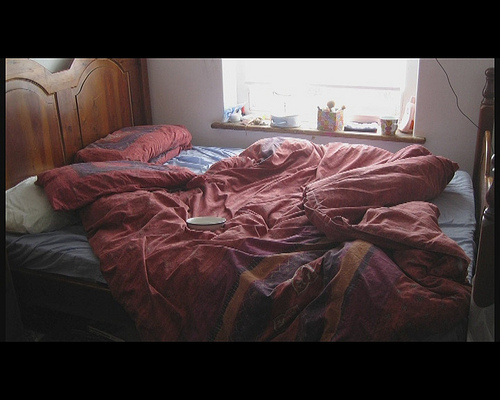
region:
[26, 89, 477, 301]
a messy unmade bed with a white bowl in it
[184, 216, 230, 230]
a white bowl on top of the duvet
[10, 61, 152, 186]
a dark wood headboard on the bed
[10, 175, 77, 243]
a white pillow near the headboard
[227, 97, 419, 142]
a bunch of stuff on the window sill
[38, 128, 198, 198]
two pillows with cases that match the duvet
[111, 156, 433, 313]
a rumpled pink duvet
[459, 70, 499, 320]
a wooden frame at the foot of the bed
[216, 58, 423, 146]
a window next to the bed with no covering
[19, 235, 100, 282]
white sheets on the mattress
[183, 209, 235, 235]
The white bowl on the bed.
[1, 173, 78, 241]
The white pillow on the bed.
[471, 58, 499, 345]
The foot board of the bed.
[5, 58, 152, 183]
The headboard on the bed.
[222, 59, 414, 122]
The window on the side of the bed.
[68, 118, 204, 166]
The burgundy pillows on the bed.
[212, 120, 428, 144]
The windowsill by the window.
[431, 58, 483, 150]
The black wire hanging by the window.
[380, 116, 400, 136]
The little mug on the windowsill on the right side.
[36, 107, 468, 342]
The burgundy quilt that is on the bed.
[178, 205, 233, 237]
White bowl with blue rim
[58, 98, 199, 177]
Pink and purple pillow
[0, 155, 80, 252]
White cloth pillow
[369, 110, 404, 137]
Multicolored ceramic cup with handle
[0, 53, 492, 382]
Bed with blankets and pillows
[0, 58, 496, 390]
Bed with messed up blankets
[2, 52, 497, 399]
Unmade bed with bowl on it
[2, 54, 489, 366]
Bed with matching blankets and pillowcases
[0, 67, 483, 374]
Bed with blue sheets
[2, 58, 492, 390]
Bed with wooden headboard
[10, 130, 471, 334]
the bed is undone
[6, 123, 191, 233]
their are three pillows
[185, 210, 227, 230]
that is a bowl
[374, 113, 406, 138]
that is a cup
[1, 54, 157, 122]
the head board is brown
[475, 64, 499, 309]
the foot board is brown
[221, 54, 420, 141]
the window has items on it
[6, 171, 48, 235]
the pillow is white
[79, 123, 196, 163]
the pillow matches the comforter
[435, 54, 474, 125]
the wire on the wall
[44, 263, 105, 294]
white line on mattress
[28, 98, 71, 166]
tan stripe on bed head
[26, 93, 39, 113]
deep mahogany on bed head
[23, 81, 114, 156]
intricate pattern on bed head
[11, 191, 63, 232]
white fluffy pillow on bed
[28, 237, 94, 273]
crumbled blue sheet on bed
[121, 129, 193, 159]
red and black pillow case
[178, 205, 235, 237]
white round bowl on bed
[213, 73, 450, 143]
large window in bedroom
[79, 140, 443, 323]
large red and brown bed spread